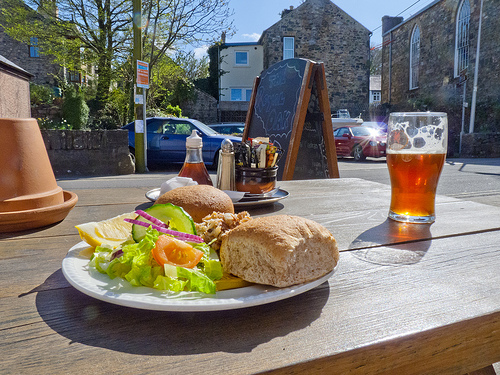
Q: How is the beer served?
A: In a glass.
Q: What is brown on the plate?
A: Bread.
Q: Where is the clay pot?
A: Left side of table.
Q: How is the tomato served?
A: Raw in a slice.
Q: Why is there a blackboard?
A: To write messages.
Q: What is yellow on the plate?
A: Lemon.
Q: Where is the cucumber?
A: Middle of plate.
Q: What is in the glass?
A: Beer.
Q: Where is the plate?
A: On the table.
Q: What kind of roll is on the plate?
A: Wheat.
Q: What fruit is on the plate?
A: Slice of lemon.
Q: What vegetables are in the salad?
A: Lettuce, tomato, cucumber, onion.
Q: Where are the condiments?
A: On a silver tray on the table.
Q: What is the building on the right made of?
A: Bricks.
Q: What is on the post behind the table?
A: Signs.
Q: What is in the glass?
A: Beer.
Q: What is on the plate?
A: Lunch.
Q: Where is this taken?
A: In the outdoors.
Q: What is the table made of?
A: Wood.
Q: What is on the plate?
A: Rolls and salad.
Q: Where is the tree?
A: Behind the cars.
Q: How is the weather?
A: Sunny and bright.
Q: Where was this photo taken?
A: At a restaurant.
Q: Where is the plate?
A: On the table.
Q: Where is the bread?
A: On the plate.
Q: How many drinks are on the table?
A: 1.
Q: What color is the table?
A: Brown.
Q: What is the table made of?
A: Wood.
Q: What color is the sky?
A: Blue.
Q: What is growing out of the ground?
A: Trees.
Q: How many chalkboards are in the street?
A: 1.